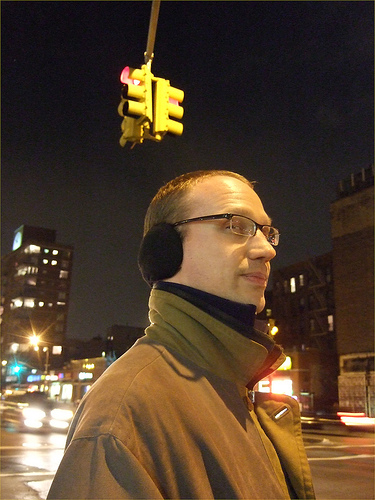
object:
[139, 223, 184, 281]
muff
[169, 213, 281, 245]
glasses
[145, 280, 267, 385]
collar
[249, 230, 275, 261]
nose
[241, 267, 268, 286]
lips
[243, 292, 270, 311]
chin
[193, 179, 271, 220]
forehead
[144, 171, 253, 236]
hair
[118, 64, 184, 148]
stoplight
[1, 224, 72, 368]
building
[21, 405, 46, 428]
car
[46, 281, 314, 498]
jacket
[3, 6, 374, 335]
sky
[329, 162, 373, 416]
other building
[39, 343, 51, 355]
street lamp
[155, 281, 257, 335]
turtleneck